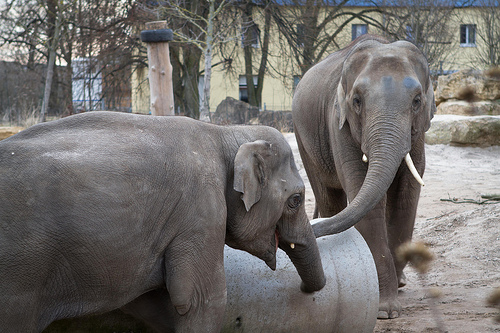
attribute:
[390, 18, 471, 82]
tree — bare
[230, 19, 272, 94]
tree — bare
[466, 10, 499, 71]
tree — bare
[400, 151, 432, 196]
tusk — curved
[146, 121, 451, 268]
elephant — smiling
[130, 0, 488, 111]
house — yellow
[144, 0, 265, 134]
tree — leafless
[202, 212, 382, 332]
tube — open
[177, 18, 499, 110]
building — yellow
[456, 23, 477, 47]
window — yellow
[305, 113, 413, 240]
trunk — gray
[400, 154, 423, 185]
tusk — short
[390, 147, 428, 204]
tusk — ivory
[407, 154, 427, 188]
tusk — white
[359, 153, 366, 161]
tusk — white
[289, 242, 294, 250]
tusk — white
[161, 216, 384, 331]
tube — cement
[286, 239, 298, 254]
tusk — ivory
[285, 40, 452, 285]
elephant — gray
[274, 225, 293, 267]
mouth — open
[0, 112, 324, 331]
elephant — big, grey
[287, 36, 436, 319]
elephant — big, grey, gray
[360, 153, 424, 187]
tusk — white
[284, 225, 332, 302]
trunk — gray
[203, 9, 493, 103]
house — yellow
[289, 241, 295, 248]
tusk — short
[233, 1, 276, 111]
tree — leafless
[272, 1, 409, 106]
tree — leafless